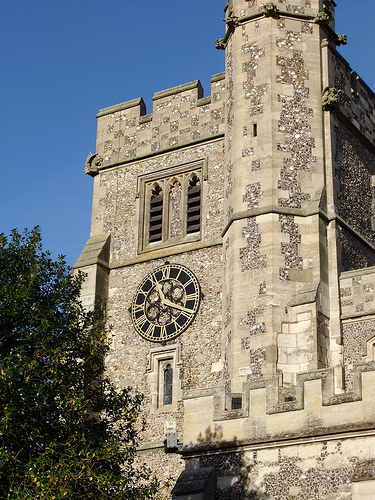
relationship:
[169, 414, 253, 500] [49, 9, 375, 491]
shade on building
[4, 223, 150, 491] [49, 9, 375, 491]
tree by building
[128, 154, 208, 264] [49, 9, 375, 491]
window on building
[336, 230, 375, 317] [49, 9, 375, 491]
balcony on building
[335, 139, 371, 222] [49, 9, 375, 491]
rocks on building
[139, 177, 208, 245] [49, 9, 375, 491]
vents on building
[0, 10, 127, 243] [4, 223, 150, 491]
sky behind trees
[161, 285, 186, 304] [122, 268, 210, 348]
circle on clock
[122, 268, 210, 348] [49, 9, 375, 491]
clock on building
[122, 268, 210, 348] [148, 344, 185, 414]
clock over window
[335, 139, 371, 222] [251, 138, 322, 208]
rocks with blocks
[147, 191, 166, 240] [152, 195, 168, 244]
panels slanted downwards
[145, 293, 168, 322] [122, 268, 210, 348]
circles on clock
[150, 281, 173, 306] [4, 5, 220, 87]
hands indicating morning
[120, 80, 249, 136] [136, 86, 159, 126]
pattern of cutouts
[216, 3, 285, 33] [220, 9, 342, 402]
figures on tower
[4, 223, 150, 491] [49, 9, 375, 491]
tree covering building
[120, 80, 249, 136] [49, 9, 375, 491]
pattern on building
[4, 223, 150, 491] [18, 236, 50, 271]
tree has leaves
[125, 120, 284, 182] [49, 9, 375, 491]
wall of building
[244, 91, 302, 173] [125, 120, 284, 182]
stones make wall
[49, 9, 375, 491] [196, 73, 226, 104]
building has opening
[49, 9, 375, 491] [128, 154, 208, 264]
building has window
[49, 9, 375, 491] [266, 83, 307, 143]
building of stone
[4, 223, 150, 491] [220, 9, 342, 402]
tree near tower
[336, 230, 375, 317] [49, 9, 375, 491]
balcony on castle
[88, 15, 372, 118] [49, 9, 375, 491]
parapets on castle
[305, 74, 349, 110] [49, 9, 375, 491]
gargoyles on building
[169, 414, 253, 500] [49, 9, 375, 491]
shadow on building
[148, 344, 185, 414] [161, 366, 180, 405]
window with glass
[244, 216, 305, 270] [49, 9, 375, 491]
decoration on building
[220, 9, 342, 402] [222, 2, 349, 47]
tower has top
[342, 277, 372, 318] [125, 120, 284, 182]
shapes on wall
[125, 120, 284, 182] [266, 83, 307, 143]
wall of stone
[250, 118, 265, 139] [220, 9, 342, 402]
hole in tower